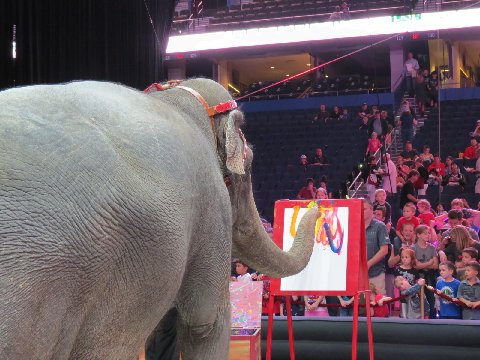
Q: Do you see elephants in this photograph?
A: Yes, there is an elephant.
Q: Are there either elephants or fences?
A: Yes, there is an elephant.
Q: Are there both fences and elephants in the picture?
A: Yes, there are both an elephant and a fence.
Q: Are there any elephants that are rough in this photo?
A: Yes, there is a rough elephant.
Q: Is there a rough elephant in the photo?
A: Yes, there is a rough elephant.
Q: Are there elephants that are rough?
A: Yes, there is an elephant that is rough.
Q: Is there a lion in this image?
A: No, there are no lions.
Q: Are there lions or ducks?
A: No, there are no lions or ducks.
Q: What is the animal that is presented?
A: The animal is an elephant.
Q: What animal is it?
A: The animal is an elephant.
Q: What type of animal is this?
A: That is an elephant.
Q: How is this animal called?
A: That is an elephant.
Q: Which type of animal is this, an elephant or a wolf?
A: That is an elephant.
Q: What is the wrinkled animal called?
A: The animal is an elephant.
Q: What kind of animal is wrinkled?
A: The animal is an elephant.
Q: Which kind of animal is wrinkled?
A: The animal is an elephant.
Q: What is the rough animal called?
A: The animal is an elephant.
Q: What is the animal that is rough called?
A: The animal is an elephant.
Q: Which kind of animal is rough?
A: The animal is an elephant.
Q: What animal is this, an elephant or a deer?
A: This is an elephant.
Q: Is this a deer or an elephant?
A: This is an elephant.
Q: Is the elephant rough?
A: Yes, the elephant is rough.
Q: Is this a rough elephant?
A: Yes, this is a rough elephant.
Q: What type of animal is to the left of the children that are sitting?
A: The animal is an elephant.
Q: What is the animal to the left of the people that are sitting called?
A: The animal is an elephant.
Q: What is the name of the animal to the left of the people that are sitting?
A: The animal is an elephant.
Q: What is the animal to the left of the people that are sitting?
A: The animal is an elephant.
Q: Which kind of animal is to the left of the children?
A: The animal is an elephant.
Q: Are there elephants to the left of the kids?
A: Yes, there is an elephant to the left of the kids.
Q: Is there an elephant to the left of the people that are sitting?
A: Yes, there is an elephant to the left of the kids.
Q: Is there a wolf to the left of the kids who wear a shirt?
A: No, there is an elephant to the left of the kids.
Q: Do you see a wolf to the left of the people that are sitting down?
A: No, there is an elephant to the left of the kids.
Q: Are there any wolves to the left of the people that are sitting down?
A: No, there is an elephant to the left of the kids.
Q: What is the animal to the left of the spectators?
A: The animal is an elephant.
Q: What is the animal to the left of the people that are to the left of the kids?
A: The animal is an elephant.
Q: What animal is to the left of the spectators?
A: The animal is an elephant.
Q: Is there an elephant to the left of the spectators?
A: Yes, there is an elephant to the left of the spectators.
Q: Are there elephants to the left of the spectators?
A: Yes, there is an elephant to the left of the spectators.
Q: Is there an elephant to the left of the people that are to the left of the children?
A: Yes, there is an elephant to the left of the spectators.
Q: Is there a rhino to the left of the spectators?
A: No, there is an elephant to the left of the spectators.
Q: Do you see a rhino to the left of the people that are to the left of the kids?
A: No, there is an elephant to the left of the spectators.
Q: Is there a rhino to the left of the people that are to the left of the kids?
A: No, there is an elephant to the left of the spectators.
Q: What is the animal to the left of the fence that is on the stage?
A: The animal is an elephant.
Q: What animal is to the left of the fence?
A: The animal is an elephant.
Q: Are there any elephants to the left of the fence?
A: Yes, there is an elephant to the left of the fence.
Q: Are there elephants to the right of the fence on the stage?
A: No, the elephant is to the left of the fence.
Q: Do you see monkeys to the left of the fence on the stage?
A: No, there is an elephant to the left of the fence.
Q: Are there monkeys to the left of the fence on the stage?
A: No, there is an elephant to the left of the fence.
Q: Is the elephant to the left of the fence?
A: Yes, the elephant is to the left of the fence.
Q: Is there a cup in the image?
A: No, there are no cups.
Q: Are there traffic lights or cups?
A: No, there are no cups or traffic lights.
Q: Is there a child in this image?
A: Yes, there are children.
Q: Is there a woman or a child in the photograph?
A: Yes, there are children.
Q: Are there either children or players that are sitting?
A: Yes, the children are sitting.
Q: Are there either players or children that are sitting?
A: Yes, the children are sitting.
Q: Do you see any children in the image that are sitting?
A: Yes, there are children that are sitting.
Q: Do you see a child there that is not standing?
A: Yes, there are children that are sitting .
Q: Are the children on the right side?
A: Yes, the children are on the right of the image.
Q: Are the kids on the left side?
A: No, the kids are on the right of the image.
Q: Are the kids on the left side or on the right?
A: The kids are on the right of the image.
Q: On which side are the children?
A: The children are on the right of the image.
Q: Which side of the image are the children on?
A: The children are on the right of the image.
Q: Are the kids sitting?
A: Yes, the kids are sitting.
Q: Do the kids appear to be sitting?
A: Yes, the kids are sitting.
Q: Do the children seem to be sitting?
A: Yes, the children are sitting.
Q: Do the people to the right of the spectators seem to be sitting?
A: Yes, the children are sitting.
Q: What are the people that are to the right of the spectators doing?
A: The children are sitting.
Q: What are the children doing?
A: The children are sitting.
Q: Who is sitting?
A: The children are sitting.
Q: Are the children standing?
A: No, the children are sitting.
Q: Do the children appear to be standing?
A: No, the children are sitting.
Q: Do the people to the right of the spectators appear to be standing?
A: No, the children are sitting.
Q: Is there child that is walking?
A: No, there are children but they are sitting.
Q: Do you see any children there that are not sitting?
A: No, there are children but they are sitting.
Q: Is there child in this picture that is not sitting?
A: No, there are children but they are sitting.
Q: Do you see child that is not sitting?
A: No, there are children but they are sitting.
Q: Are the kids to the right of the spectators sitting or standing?
A: The kids are sitting.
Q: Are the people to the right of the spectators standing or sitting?
A: The kids are sitting.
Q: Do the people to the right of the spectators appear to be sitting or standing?
A: The kids are sitting.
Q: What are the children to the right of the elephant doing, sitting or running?
A: The kids are sitting.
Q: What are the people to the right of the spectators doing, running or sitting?
A: The kids are sitting.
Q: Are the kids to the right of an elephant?
A: Yes, the kids are to the right of an elephant.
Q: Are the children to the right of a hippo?
A: No, the children are to the right of an elephant.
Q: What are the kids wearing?
A: The kids are wearing a shirt.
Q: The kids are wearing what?
A: The kids are wearing a shirt.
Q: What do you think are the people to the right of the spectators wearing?
A: The kids are wearing a shirt.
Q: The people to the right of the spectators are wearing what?
A: The kids are wearing a shirt.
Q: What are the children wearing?
A: The kids are wearing a shirt.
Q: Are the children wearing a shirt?
A: Yes, the children are wearing a shirt.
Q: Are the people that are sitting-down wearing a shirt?
A: Yes, the children are wearing a shirt.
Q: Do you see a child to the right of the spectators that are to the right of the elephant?
A: Yes, there are children to the right of the spectators.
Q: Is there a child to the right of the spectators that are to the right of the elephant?
A: Yes, there are children to the right of the spectators.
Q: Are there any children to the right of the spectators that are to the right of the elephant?
A: Yes, there are children to the right of the spectators.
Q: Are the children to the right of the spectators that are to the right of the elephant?
A: Yes, the children are to the right of the spectators.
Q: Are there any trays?
A: No, there are no trays.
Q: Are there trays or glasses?
A: No, there are no trays or glasses.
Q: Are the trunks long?
A: Yes, the trunks are long.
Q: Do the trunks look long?
A: Yes, the trunks are long.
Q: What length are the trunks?
A: The trunks are long.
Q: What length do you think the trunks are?
A: The trunks are long.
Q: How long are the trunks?
A: The trunks are long.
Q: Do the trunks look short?
A: No, the trunks are long.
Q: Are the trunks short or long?
A: The trunks are long.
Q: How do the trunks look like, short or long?
A: The trunks are long.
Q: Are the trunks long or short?
A: The trunks are long.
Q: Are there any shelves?
A: No, there are no shelves.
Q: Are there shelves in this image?
A: No, there are no shelves.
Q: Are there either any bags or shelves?
A: No, there are no shelves or bags.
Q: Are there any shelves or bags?
A: No, there are no shelves or bags.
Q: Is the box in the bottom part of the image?
A: Yes, the box is in the bottom of the image.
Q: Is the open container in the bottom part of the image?
A: Yes, the box is in the bottom of the image.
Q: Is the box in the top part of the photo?
A: No, the box is in the bottom of the image.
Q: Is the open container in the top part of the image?
A: No, the box is in the bottom of the image.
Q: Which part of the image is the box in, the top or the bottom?
A: The box is in the bottom of the image.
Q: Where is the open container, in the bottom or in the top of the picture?
A: The box is in the bottom of the image.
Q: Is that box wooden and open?
A: Yes, the box is wooden and open.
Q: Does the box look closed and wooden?
A: No, the box is wooden but open.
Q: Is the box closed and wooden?
A: No, the box is wooden but open.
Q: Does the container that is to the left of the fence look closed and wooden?
A: No, the box is wooden but open.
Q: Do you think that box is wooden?
A: Yes, the box is wooden.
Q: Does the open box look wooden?
A: Yes, the box is wooden.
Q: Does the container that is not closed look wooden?
A: Yes, the box is wooden.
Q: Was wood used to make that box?
A: Yes, the box is made of wood.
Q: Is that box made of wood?
A: Yes, the box is made of wood.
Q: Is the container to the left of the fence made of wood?
A: Yes, the box is made of wood.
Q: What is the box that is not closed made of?
A: The box is made of wood.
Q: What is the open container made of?
A: The box is made of wood.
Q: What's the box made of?
A: The box is made of wood.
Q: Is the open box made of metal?
A: No, the box is made of wood.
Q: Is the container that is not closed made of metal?
A: No, the box is made of wood.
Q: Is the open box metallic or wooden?
A: The box is wooden.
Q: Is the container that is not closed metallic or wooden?
A: The box is wooden.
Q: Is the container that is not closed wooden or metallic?
A: The box is wooden.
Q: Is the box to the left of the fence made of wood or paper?
A: The box is made of wood.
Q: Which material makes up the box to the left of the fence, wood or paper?
A: The box is made of wood.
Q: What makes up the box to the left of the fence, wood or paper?
A: The box is made of wood.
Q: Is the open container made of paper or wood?
A: The box is made of wood.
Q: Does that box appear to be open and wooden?
A: Yes, the box is open and wooden.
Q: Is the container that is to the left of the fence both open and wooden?
A: Yes, the box is open and wooden.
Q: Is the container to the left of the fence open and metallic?
A: No, the box is open but wooden.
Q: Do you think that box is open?
A: Yes, the box is open.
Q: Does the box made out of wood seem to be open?
A: Yes, the box is open.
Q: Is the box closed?
A: No, the box is open.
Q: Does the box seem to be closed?
A: No, the box is open.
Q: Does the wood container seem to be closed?
A: No, the box is open.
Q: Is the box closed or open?
A: The box is open.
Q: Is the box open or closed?
A: The box is open.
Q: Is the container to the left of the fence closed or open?
A: The box is open.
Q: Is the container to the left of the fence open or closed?
A: The box is open.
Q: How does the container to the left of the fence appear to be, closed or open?
A: The box is open.